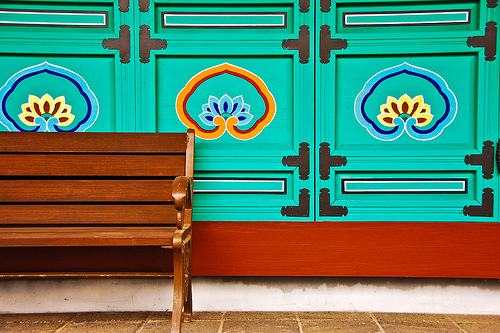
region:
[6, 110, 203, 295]
the bench is brown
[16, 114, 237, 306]
the wooden bench is brown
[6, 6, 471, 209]
green wall behind bench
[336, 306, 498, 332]
brown tile on floor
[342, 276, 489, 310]
white wall above tile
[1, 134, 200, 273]
bench is brown and wood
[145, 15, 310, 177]
light green painted wall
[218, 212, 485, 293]
dark brown wall near floor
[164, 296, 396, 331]
white grout on tile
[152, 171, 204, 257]
decorative arm on bench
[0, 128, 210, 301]
bench is obscuring wall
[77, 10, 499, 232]
wall looks like doors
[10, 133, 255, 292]
a bench in front of a wall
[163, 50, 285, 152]
an orange design on a green wall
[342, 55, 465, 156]
a blue and yellow design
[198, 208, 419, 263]
red on base of wall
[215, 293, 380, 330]
brick pavement in front of wall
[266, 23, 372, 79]
a brown inlay on wall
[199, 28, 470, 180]
a decorative wall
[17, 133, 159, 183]
slats on the bench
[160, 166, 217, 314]
arm rest on bench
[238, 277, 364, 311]
concrete unpainted under colors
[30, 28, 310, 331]
a bench on the sidewalk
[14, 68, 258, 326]
a brown bench on the sidewalk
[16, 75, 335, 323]
a sidewalk with bench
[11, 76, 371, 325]
a sidewalk with brown bench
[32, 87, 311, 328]
a bench against the wall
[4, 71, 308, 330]
a brown bench against the wall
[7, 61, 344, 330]
a wall with a bench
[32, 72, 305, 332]
a wall with a brown bench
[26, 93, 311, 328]
a sidewalk with a bench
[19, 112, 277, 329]
a sidewalk with a brown bench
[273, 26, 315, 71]
Silver hardware on a wall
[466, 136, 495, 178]
Silver hardware on a wall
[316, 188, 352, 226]
Silver hardware on a wall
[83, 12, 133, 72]
Silver hardware on a wall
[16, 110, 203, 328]
Dark brown wooden bench